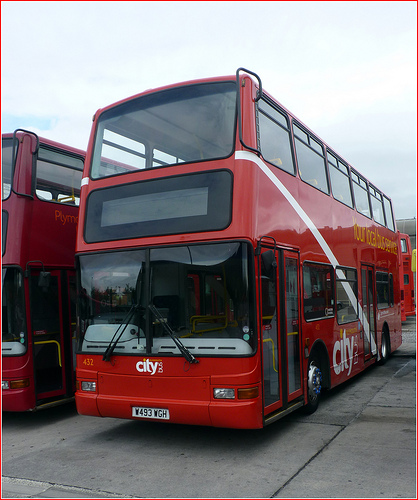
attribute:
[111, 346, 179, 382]
logo — white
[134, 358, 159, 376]
word — white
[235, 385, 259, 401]
reflector — small, orange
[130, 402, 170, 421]
license plate — white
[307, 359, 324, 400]
rims — silver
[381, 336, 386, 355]
rims — silver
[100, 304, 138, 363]
blades — black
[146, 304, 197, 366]
blades — black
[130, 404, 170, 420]
license plate — black and white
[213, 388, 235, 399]
headlight — small, square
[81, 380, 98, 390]
headlight — small, square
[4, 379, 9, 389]
headlight — small, square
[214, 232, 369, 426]
doors — double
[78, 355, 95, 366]
numbers — yellow 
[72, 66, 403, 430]
busses — double decker, black and red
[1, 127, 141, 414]
busses — double decker, black and red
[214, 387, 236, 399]
headlight — white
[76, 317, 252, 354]
dashboard — white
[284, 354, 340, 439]
tire — black 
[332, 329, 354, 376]
word — white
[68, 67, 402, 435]
bus — red, double decker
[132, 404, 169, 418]
plate — white, black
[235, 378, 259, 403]
signal — orange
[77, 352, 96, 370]
numbers — yellow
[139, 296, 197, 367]
wiper — black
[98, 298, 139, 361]
wiper — black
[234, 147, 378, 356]
stripe — white